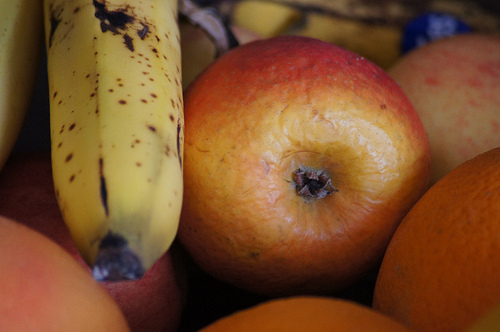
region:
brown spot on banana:
[61, 170, 85, 185]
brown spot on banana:
[57, 145, 80, 164]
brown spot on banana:
[55, 136, 67, 148]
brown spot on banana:
[63, 120, 83, 132]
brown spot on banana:
[89, 104, 112, 122]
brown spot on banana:
[133, 156, 143, 171]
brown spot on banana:
[128, 129, 143, 150]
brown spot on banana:
[142, 115, 159, 135]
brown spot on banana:
[154, 133, 172, 165]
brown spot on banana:
[84, 2, 158, 56]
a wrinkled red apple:
[177, 36, 431, 291]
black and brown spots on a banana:
[41, 3, 184, 282]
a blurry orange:
[193, 296, 403, 329]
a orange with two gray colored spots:
[376, 145, 498, 328]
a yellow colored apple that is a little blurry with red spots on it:
[388, 33, 496, 195]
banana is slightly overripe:
[44, 0, 184, 284]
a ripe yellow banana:
[1, 2, 41, 164]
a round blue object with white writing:
[399, 8, 464, 55]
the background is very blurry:
[184, 0, 498, 73]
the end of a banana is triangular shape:
[89, 227, 144, 284]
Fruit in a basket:
[8, 0, 453, 328]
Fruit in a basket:
[316, 13, 488, 312]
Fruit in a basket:
[7, 184, 498, 330]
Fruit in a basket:
[1, 2, 197, 329]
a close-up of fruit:
[1, 1, 487, 327]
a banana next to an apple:
[35, 0, 185, 275]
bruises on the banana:
[90, 5, 150, 50]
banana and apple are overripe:
[35, 0, 437, 275]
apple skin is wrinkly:
[180, 40, 420, 280]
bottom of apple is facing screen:
[200, 40, 400, 280]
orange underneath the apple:
[195, 290, 405, 327]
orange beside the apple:
[370, 145, 496, 325]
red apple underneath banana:
[26, 166, 181, 317]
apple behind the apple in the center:
[397, 42, 498, 169]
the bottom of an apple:
[187, 43, 435, 278]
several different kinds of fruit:
[4, 3, 488, 323]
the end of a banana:
[85, 235, 144, 290]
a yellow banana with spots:
[31, 1, 191, 278]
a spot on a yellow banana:
[66, 120, 75, 135]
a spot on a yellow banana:
[61, 148, 77, 165]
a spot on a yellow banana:
[116, 98, 132, 111]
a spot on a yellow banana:
[145, 120, 157, 135]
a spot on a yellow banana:
[91, 47, 102, 59]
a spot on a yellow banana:
[148, 74, 156, 85]